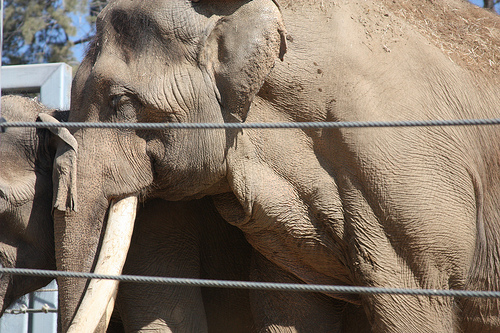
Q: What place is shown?
A: It is a pen.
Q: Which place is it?
A: It is a pen.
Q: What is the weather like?
A: It is clear.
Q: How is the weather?
A: It is clear.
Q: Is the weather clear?
A: Yes, it is clear.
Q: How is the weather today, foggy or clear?
A: It is clear.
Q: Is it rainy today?
A: No, it is clear.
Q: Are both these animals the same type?
A: Yes, all the animals are elephants.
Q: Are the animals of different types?
A: No, all the animals are elephants.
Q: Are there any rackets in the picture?
A: No, there are no rackets.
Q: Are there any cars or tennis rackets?
A: No, there are no tennis rackets or cars.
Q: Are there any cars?
A: No, there are no cars.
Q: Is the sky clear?
A: Yes, the sky is clear.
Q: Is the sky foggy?
A: No, the sky is clear.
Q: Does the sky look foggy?
A: No, the sky is clear.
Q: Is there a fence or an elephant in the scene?
A: Yes, there is an elephant.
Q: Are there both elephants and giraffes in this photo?
A: No, there is an elephant but no giraffes.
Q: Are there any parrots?
A: No, there are no parrots.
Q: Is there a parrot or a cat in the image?
A: No, there are no parrots or cats.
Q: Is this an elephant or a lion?
A: This is an elephant.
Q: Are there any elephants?
A: Yes, there is an elephant.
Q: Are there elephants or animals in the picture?
A: Yes, there is an elephant.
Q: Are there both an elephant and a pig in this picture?
A: No, there is an elephant but no pigs.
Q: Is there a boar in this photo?
A: No, there are no boars.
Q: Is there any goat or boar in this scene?
A: No, there are no boars or goats.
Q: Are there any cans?
A: No, there are no cans.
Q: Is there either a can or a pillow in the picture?
A: No, there are no cans or pillows.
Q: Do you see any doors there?
A: Yes, there is a door.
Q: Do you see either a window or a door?
A: Yes, there is a door.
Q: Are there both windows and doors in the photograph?
A: No, there is a door but no windows.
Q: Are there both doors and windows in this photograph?
A: No, there is a door but no windows.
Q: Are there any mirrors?
A: No, there are no mirrors.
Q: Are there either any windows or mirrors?
A: No, there are no mirrors or windows.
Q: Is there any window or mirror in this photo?
A: No, there are no mirrors or windows.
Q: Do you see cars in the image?
A: No, there are no cars.